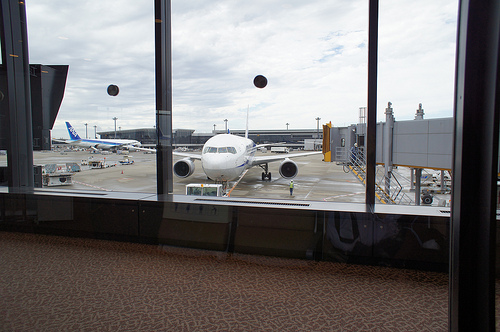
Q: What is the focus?
A: Plane getting ready to board.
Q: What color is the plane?
A: White.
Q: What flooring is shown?
A: Carpet.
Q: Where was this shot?
A: Terminal.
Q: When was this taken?
A: Daytime.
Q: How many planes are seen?
A: 2.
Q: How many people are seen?
A: 0.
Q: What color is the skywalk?
A: Grey.